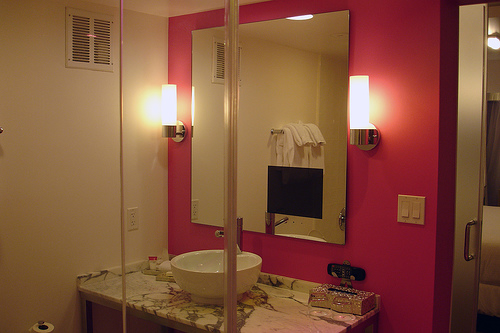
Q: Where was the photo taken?
A: In a restroom.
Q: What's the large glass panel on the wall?
A: A mirror.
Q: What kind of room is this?
A: Bathroom.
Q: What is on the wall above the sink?
A: Mirror.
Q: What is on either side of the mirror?
A: Wall lamps.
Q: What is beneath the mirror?
A: White sink.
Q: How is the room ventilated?
A: Wall vent in upper left hand corner.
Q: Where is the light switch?
A: On the wall near the door.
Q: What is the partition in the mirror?
A: Gold.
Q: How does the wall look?
A: White.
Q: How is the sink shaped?
A: Round.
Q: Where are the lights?
A: On the sides of the mirror.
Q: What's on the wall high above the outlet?
A: A vent.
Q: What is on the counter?
A: A round sink.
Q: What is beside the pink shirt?
A: A tissue box.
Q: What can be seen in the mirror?
A: A reflection.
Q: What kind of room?
A: Bathroom.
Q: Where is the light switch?
A: On the pink wall.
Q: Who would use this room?
A: Someone needing to use the bathroom.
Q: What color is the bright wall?
A: Deep reddish pink.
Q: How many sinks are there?
A: One.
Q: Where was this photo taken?
A: In the bathroom.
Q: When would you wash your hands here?
A: When they are dirty.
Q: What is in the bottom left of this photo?
A: Toilet paper.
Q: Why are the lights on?
A: The room is dark.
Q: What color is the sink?
A: White.